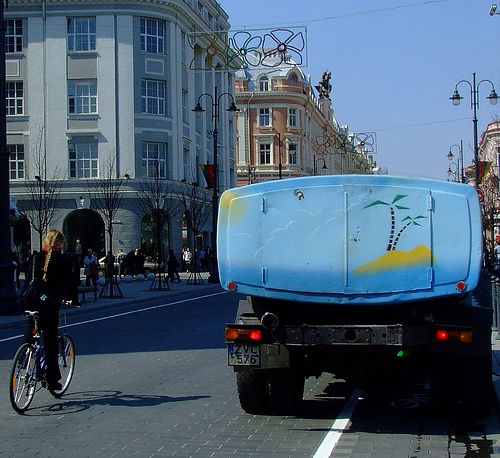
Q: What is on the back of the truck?
A: A beach scene.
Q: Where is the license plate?
A: On the left.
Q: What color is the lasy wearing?
A: Black.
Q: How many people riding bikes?
A: One.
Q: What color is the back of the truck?
A: Blue.